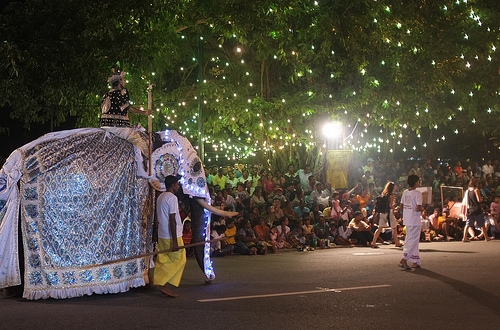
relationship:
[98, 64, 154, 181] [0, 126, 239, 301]
person riding elephant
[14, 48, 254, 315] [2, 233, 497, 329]
elephant walking on road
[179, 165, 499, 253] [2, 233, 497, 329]
people sitting next to road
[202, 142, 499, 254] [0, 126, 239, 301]
people enjoying elephant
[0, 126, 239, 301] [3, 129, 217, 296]
elephant wearing costume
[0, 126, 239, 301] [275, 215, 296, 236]
elephant entertaining person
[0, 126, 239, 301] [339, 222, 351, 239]
elephant entertaining person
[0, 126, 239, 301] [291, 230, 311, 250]
elephant entertaining person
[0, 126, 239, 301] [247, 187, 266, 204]
elephant entertaining person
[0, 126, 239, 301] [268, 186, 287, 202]
elephant entertaining person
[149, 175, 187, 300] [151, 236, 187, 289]
man in bottoms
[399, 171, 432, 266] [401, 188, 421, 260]
woman in dress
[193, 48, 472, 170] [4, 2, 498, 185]
lights in trees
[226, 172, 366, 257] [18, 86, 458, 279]
people watching parade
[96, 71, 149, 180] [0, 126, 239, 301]
handler atop elephant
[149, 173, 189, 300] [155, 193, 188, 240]
man wearing shirt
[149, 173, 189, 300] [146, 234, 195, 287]
man wearing bottoms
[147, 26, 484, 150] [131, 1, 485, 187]
lights hanging from tree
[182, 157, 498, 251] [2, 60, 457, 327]
spectators at parade